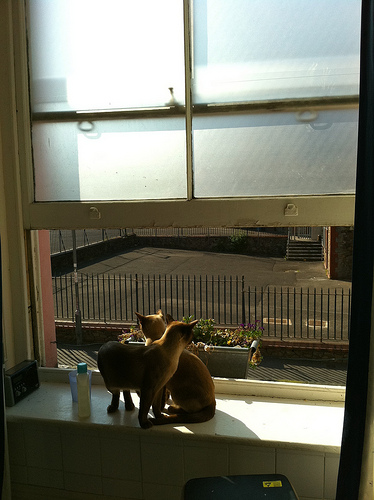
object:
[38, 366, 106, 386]
window sill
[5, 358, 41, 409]
black radio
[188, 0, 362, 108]
glass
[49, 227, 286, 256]
fence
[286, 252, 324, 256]
stairs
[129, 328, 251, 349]
ground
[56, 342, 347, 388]
fence shadow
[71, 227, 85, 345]
pole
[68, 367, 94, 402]
glass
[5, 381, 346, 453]
ledge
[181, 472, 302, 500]
trash can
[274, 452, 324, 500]
tile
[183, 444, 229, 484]
tile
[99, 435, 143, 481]
tile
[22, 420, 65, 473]
tile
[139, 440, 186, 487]
tile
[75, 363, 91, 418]
bottle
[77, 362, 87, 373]
blue lid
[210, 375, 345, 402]
windowsill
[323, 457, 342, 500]
tiles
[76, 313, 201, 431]
bottle cats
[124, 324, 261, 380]
planter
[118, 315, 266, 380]
garden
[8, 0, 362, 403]
window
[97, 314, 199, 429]
cat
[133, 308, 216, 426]
cat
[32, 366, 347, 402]
edge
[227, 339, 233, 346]
flowers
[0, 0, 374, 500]
building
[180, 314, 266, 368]
plants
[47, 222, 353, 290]
background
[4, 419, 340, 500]
wall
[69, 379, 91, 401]
liquid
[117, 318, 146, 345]
plants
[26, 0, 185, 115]
paper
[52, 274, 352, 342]
fence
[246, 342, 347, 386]
ground